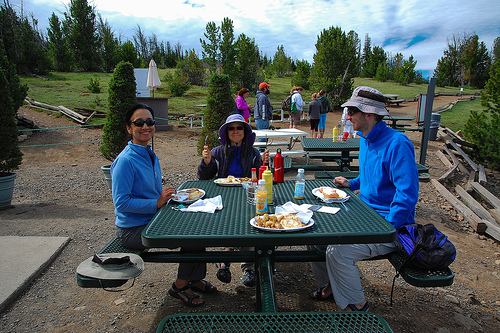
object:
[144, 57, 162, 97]
umbrella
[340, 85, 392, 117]
hat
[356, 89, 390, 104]
stripe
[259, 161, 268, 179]
bottle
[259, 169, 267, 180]
ketchup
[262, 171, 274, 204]
mustard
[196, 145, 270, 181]
sweater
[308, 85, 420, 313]
man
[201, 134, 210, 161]
fork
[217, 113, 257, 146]
hat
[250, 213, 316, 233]
plate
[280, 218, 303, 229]
food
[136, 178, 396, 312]
table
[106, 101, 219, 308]
people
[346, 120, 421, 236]
clothes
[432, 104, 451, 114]
edges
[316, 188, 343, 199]
meal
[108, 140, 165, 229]
jacket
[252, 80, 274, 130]
man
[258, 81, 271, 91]
hat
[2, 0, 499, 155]
background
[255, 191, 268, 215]
drinks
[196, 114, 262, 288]
female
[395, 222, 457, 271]
backpack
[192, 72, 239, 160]
trees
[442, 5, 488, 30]
clouds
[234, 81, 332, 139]
six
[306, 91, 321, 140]
standing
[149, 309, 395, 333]
bench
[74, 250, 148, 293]
hat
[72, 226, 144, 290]
bench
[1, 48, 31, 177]
tree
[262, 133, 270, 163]
knife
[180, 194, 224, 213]
napkin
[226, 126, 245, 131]
sunglasses